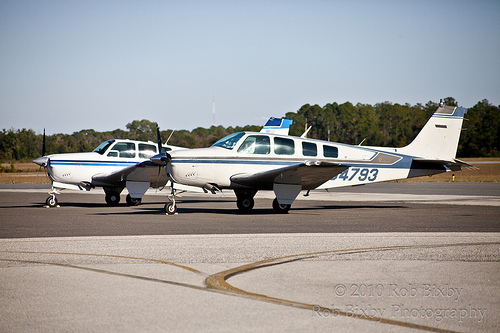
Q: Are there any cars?
A: No, there are no cars.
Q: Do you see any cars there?
A: No, there are no cars.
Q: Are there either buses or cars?
A: No, there are no cars or buses.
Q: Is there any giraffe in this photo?
A: No, there are no giraffes.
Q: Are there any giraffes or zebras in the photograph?
A: No, there are no giraffes or zebras.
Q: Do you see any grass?
A: Yes, there is grass.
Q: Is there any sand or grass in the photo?
A: Yes, there is grass.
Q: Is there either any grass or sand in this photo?
A: Yes, there is grass.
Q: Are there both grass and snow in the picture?
A: No, there is grass but no snow.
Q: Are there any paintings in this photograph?
A: No, there are no paintings.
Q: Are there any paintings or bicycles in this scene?
A: No, there are no paintings or bicycles.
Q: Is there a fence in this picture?
A: No, there are no fences.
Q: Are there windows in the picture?
A: Yes, there is a window.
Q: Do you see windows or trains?
A: Yes, there is a window.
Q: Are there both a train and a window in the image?
A: No, there is a window but no trains.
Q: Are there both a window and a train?
A: No, there is a window but no trains.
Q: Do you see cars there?
A: No, there are no cars.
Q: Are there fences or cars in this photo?
A: No, there are no cars or fences.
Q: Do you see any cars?
A: No, there are no cars.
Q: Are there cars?
A: No, there are no cars.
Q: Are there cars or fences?
A: No, there are no cars or fences.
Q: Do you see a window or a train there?
A: Yes, there is a window.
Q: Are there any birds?
A: No, there are no birds.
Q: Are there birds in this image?
A: No, there are no birds.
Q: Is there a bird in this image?
A: No, there are no birds.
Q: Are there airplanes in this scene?
A: Yes, there is an airplane.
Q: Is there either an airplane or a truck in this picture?
A: Yes, there is an airplane.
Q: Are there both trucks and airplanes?
A: No, there is an airplane but no trucks.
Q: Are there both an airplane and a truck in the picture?
A: No, there is an airplane but no trucks.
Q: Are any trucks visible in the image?
A: No, there are no trucks.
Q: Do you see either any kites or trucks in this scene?
A: No, there are no trucks or kites.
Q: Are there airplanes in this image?
A: Yes, there is an airplane.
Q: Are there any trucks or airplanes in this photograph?
A: Yes, there is an airplane.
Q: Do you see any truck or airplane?
A: Yes, there is an airplane.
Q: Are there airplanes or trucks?
A: Yes, there is an airplane.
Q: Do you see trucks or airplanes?
A: Yes, there is an airplane.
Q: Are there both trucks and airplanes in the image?
A: No, there is an airplane but no trucks.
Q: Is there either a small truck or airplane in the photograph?
A: Yes, there is a small airplane.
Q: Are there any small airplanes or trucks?
A: Yes, there is a small airplane.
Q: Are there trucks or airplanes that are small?
A: Yes, the airplane is small.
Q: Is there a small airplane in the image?
A: Yes, there is a small airplane.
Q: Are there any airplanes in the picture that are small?
A: Yes, there is an airplane that is small.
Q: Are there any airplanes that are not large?
A: Yes, there is a small airplane.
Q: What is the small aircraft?
A: The aircraft is an airplane.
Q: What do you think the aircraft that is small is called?
A: The aircraft is an airplane.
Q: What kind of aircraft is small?
A: The aircraft is an airplane.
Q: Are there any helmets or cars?
A: No, there are no cars or helmets.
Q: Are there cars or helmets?
A: No, there are no cars or helmets.